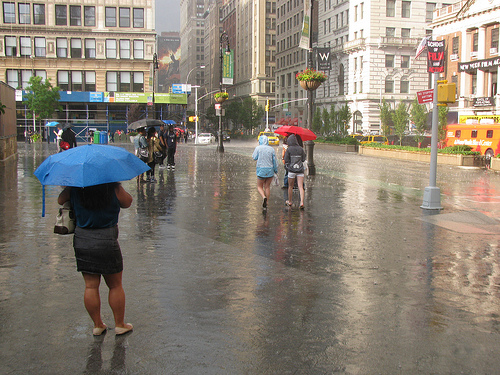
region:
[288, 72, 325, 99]
basket of flowers hang on a pole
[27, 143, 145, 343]
woman carries a bright blue umbrella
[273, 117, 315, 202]
young girl follows red umbrella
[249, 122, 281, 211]
girl wears blue jacket with hood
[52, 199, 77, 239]
white and brown handbag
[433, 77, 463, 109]
back of a yellow crosswalk light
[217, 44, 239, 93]
greemn and white banner on pole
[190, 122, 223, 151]
white car turns a corner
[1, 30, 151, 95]
white window shades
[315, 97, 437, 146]
a line of young trees along the sidewalk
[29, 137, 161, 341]
woman carrying blue umbrella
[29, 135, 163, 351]
woman wearing black shirt and skirt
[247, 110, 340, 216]
girls in shorts caught in rain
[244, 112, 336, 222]
pedestrians walking on sidewalk in rain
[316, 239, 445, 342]
rain drops splashing on sidewalk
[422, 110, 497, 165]
bus stopped across the street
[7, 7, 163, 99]
brick building with rows of windows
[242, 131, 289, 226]
girl wearing shorts and hooded sweatshirt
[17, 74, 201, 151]
scaffolding for construction work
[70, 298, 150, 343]
beige flat shoes for women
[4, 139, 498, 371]
The street is very wet.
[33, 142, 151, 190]
The umbrella is blue.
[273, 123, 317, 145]
The umbrella is red.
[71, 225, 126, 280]
The woman is wearing a short skirt.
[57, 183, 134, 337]
The woman's head is hidden from view.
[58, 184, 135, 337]
The woman has dark skin.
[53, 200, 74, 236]
The woman is carrying a handbag.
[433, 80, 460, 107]
The crosswalk light is yellow.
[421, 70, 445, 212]
The pole is gray.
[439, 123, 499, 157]
The truck is orange.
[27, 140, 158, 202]
blue umbrella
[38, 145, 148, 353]
woman standing under blue umbrella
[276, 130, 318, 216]
girl wearing grey hoodie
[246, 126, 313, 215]
two girls walking in rain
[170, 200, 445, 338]
wet concrete ground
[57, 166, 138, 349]
woman wearing black skirt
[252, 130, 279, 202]
girl wearing blue hoodie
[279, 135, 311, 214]
girl wearing shorts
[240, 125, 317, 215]
two girls walking on wet ground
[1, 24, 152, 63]
windows on a building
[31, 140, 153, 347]
The woman is holding an umbrella.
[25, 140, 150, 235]
The umbrella is blue.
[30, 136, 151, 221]
The umbrella is open.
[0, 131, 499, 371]
The street is wet.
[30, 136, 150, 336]
The woman is wearing a skirt.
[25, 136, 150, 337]
The skirt is black.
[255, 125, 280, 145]
The car is yellow.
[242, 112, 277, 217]
The girl is walking.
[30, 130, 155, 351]
The woman is standing.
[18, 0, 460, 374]
It is raining outside.